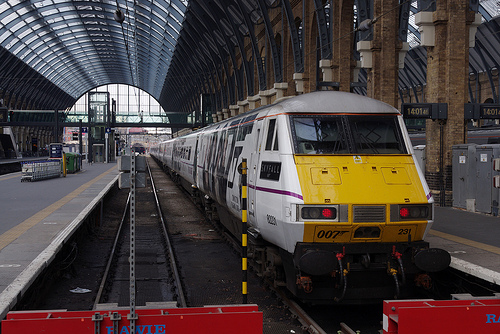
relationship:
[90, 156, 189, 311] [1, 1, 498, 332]
tracks in train station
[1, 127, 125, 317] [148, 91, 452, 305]
terminal for train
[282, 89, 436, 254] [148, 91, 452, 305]
front of train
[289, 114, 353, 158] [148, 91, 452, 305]
window of train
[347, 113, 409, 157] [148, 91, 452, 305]
window of train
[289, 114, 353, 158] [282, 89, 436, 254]
window on front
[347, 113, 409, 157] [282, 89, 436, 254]
window on front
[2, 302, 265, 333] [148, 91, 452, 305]
bumper for train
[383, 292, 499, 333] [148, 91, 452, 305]
bumper for train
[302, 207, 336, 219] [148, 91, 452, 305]
light on train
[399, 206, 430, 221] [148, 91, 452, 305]
light on train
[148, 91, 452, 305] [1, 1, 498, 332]
train in train station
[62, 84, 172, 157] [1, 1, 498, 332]
outside of train station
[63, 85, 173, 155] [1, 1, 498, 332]
opening at train station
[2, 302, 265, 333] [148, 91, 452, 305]
bumper in front of train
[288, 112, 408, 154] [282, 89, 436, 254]
windshield on front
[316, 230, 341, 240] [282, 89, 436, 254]
007 on front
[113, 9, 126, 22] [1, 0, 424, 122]
light in ceiling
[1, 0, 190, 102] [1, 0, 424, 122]
middle of ceiling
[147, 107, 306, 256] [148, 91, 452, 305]
side of train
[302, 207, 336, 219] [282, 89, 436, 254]
light on front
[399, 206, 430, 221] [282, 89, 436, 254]
light on front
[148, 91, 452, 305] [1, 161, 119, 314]
train at platform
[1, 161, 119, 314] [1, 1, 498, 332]
platform in train station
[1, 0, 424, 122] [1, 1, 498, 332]
ceiling of train station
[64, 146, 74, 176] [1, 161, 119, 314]
garbage bin on platform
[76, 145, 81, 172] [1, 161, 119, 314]
garbage bin on platform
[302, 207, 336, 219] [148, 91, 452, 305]
light of train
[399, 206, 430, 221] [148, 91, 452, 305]
light of train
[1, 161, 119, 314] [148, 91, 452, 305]
platform for train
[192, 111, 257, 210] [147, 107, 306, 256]
advertising on side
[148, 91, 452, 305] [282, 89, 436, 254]
train with front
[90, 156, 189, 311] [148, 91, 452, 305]
tracks for train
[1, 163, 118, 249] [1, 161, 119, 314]
stripe on platform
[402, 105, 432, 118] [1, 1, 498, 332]
sign of train station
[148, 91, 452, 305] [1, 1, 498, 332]
train at train station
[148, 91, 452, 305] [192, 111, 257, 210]
train has advertising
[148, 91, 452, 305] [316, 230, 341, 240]
train has 007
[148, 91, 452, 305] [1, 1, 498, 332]
train through train station